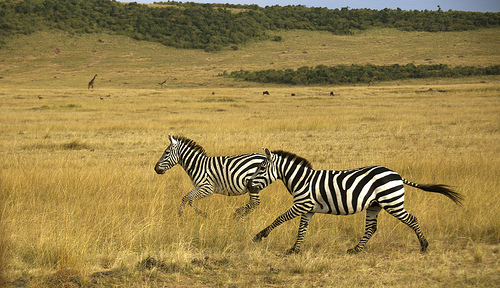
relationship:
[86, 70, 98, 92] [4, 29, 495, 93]
giraffe in background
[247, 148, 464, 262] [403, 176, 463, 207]
zebra has tail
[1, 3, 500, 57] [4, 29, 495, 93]
bushes in background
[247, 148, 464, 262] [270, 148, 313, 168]
zebra has mane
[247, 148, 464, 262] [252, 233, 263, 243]
zebra has hoof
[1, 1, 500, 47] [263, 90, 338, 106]
hill behind animals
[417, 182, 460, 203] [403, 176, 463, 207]
hair on tail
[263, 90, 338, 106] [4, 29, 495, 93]
animals in background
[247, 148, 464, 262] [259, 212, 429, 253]
zebra has legs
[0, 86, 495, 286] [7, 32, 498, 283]
grass in field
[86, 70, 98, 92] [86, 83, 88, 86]
giraffe has tail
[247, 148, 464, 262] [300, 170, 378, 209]
zebra has stripes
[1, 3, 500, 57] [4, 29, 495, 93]
trees in background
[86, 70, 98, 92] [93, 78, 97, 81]
giraffe has neck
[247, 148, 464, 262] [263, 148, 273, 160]
zebra has ears